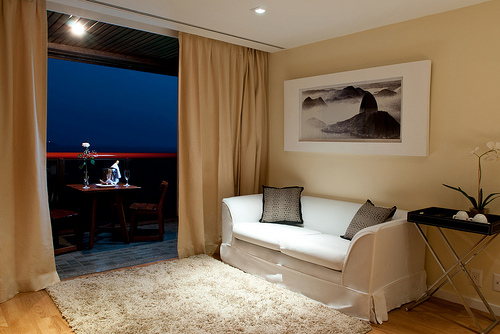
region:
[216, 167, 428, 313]
couch against the wall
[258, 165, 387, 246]
pillows on the couch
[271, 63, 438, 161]
image on the wall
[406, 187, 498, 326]
stand against the wall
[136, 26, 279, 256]
curtain to outside terrace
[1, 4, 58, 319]
curtain to the terrace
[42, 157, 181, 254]
table and chairs outside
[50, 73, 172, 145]
view of the outside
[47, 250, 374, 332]
rug on the floor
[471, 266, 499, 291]
outlets on the wall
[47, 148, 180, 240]
red metal balcony barrier gate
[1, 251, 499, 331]
light wooden flooring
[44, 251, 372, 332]
beige shag area rug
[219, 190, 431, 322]
solid white rounded arms and back couch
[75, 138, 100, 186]
a single pink rose in a crystal vase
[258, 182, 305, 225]
black and grey throw pillow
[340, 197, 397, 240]
black and grey throw pillow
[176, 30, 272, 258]
floor to ceiling beige curtains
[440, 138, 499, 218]
orchid stem in a planter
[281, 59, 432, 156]
black and white art print with a white frame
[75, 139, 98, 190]
White flower in vase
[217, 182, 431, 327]
Two pillows on white couch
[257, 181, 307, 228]
Gray pillow with black trim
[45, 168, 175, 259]
Dining table and chairs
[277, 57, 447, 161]
White framed art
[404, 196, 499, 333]
Black serving tray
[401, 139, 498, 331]
White flower on serving tray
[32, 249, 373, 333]
Beige living room rug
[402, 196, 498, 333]
Two white cups on serving tray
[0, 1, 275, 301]
Beige window curtains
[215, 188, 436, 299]
A couch in the photo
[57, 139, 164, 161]
A red metal bar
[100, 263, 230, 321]
A carpet in the photo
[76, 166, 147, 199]
A table in the room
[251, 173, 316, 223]
A pillow on the couch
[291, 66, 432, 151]
A wall hanging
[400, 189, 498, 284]
A stand in the photo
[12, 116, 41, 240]
Curtains on the door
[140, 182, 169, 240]
A chair in the room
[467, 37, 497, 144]
A wall in the photo